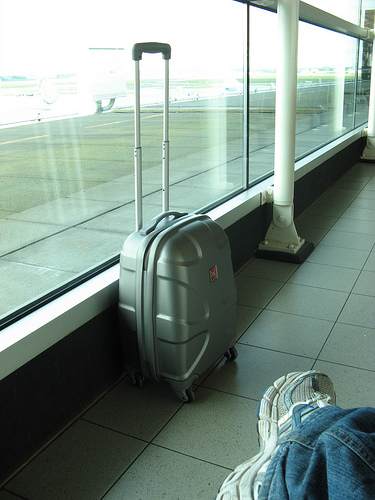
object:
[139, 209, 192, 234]
handle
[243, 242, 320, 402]
floor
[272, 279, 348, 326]
while tile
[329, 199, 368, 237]
while tile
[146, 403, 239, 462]
while tile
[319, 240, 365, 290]
while tile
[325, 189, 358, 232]
white tile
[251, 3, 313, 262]
pole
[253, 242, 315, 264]
base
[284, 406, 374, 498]
leg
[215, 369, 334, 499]
foot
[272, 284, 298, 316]
tile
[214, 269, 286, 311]
tile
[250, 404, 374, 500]
jean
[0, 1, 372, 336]
windows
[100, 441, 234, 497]
tile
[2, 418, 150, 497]
tile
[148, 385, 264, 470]
tile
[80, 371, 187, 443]
tile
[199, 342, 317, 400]
tile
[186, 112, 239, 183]
tile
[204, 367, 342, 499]
sneaker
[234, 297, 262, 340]
floor tile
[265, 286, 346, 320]
floor tile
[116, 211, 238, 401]
luggage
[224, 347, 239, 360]
wheel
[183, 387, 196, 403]
wheel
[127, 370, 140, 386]
wheel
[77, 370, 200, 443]
tile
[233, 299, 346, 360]
tile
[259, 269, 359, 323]
tile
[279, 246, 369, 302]
tile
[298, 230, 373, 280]
tile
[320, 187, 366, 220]
tile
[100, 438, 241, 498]
tile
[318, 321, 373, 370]
tile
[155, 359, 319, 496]
side